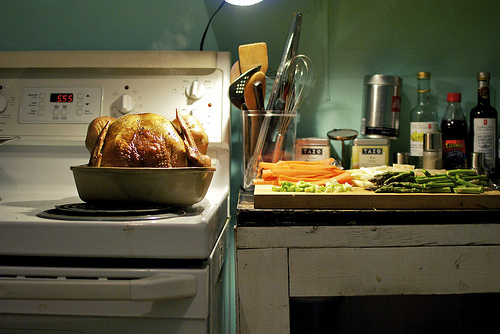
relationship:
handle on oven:
[0, 275, 196, 299] [0, 44, 221, 331]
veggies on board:
[254, 157, 499, 194] [252, 175, 498, 211]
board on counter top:
[243, 175, 498, 222] [235, 181, 498, 223]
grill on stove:
[48, 201, 182, 222] [2, 185, 214, 257]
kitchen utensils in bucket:
[227, 10, 315, 190] [244, 17, 323, 179]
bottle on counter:
[416, 69, 438, 167] [239, 159, 485, 229]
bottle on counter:
[439, 90, 464, 162] [239, 159, 485, 229]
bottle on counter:
[462, 67, 492, 174] [239, 159, 485, 229]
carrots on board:
[250, 160, 352, 183] [252, 174, 497, 214]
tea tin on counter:
[352, 136, 390, 167] [239, 174, 498, 226]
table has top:
[235, 162, 499, 331] [234, 187, 499, 226]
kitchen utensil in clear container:
[270, 53, 315, 163] [241, 109, 297, 194]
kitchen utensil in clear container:
[243, 10, 302, 187] [241, 109, 297, 194]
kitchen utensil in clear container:
[252, 79, 266, 128] [241, 109, 297, 194]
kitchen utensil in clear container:
[243, 70, 265, 156] [241, 109, 297, 194]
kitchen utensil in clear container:
[228, 65, 260, 157] [241, 109, 297, 194]